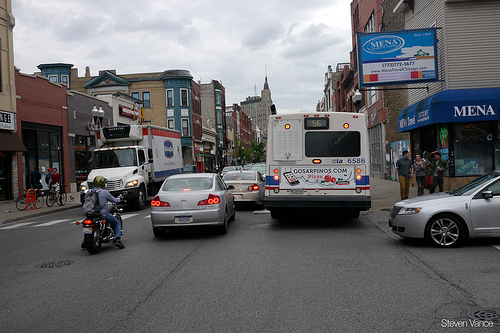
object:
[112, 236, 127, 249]
shoes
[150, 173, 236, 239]
silver car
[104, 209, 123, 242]
pants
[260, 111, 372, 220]
bus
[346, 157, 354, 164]
numbers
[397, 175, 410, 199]
pants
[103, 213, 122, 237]
pants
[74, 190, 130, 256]
motorcycle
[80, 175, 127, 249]
man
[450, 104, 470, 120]
letters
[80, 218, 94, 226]
taillight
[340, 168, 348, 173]
letters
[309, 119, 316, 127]
numbers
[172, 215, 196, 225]
plate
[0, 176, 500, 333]
road